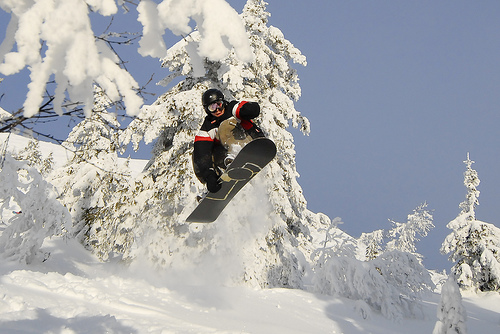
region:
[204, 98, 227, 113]
goggles on the face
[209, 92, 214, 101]
dot on the helmet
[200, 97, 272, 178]
the person is surfboarder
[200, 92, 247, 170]
the person is crouched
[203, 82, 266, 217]
person in the air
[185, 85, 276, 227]
the person is making a jump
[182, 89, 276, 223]
the guy is holding his skating board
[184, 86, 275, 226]
the guy is wearing goggles to protect his eyes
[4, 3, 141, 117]
leaves are not visible as they are inside the snow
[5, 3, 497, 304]
trees are covered with snow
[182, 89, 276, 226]
the person is wearing gloves in his hand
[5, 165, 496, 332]
shadows are visible in the white snow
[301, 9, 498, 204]
the sky is so clear without any clouds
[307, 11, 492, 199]
the sky is blue in color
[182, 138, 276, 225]
bottom of the skating snow board is black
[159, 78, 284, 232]
a person on a snowboard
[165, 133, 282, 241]
a black snowboard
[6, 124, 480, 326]
a snowy mountain side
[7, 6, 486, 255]
a clear blue sky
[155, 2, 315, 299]
a tree covered in snow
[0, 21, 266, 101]
snowy tree branches hanging down from overhead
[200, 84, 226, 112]
a black helmet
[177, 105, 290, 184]
a black, white and red jacket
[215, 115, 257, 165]
a pair of brown snow pants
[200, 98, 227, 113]
a pair of ski goggles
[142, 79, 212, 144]
snow is on the limbs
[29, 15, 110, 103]
snow is on the leaves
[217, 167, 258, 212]
the design is gold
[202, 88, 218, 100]
the helmet is black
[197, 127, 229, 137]
stripes on the jacket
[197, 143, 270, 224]
the board is black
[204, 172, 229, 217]
hand on the board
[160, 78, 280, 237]
Man on a snowboard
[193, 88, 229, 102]
man wearing a black helmet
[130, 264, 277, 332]
snow on the ground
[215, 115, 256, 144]
man wearing brown pants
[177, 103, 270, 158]
man wearing a black jacket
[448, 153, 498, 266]
snow on the tree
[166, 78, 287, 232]
man in the air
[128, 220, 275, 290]
snow spraying in the air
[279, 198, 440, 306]
snow covering the landscape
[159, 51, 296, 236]
person doing a trick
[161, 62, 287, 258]
person is mid air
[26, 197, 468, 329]
snow on the ground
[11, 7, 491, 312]
snow on the trees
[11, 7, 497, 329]
a bright and clear day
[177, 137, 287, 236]
this is a snowboard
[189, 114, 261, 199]
person has knees bent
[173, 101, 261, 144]
red and white trim on jacket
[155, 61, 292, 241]
person on a snowboard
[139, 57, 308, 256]
person in mid air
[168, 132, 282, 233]
a black and yellow snowboard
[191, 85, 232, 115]
person wearing a black helmet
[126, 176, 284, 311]
snow falling from board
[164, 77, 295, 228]
Man on a snow board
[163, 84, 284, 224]
Man snowboarding through the air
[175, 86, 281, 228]
Man is wearing goggles.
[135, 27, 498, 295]
Trees covered in snow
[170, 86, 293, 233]
Man doing tricks on his snow board.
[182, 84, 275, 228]
Snowboarder wearing black, white, and red.